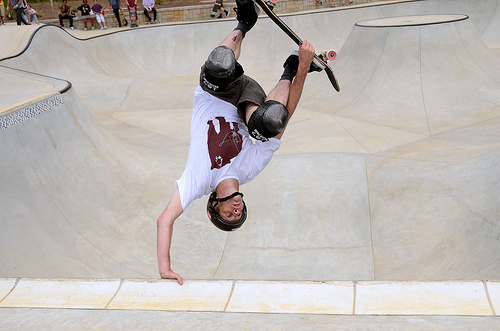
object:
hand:
[158, 269, 183, 286]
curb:
[0, 276, 500, 283]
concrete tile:
[0, 278, 123, 311]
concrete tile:
[104, 277, 236, 312]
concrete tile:
[223, 278, 353, 316]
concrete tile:
[353, 280, 499, 315]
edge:
[0, 306, 500, 317]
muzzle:
[216, 155, 219, 158]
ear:
[210, 166, 215, 171]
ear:
[229, 161, 232, 164]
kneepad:
[204, 45, 235, 79]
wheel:
[325, 49, 337, 59]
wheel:
[269, 0, 277, 4]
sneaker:
[235, 0, 260, 25]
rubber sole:
[247, 0, 262, 17]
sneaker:
[281, 48, 325, 76]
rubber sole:
[291, 50, 327, 70]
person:
[91, 0, 108, 30]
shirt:
[91, 4, 102, 12]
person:
[124, 0, 139, 27]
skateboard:
[129, 8, 138, 27]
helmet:
[206, 189, 248, 232]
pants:
[96, 14, 106, 23]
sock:
[279, 69, 296, 84]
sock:
[232, 22, 250, 39]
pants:
[198, 59, 267, 127]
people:
[0, 0, 7, 29]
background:
[0, 0, 499, 330]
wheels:
[321, 49, 337, 60]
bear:
[206, 115, 243, 170]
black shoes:
[232, 0, 326, 82]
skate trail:
[0, 1, 499, 311]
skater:
[132, 23, 137, 28]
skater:
[88, 27, 94, 31]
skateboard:
[255, 0, 342, 93]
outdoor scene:
[0, 0, 499, 331]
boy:
[155, 1, 324, 286]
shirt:
[174, 83, 283, 213]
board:
[249, 0, 341, 92]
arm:
[156, 188, 184, 273]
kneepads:
[200, 44, 292, 144]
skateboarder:
[154, 0, 340, 285]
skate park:
[0, 1, 499, 331]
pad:
[200, 45, 245, 93]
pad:
[247, 98, 291, 143]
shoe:
[231, 0, 260, 33]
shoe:
[280, 50, 327, 78]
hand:
[298, 40, 317, 67]